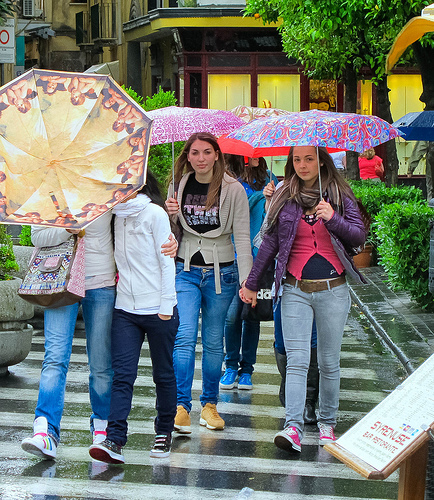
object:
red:
[402, 434, 411, 442]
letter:
[370, 420, 381, 432]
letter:
[376, 424, 388, 436]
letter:
[382, 424, 391, 438]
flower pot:
[0, 273, 35, 376]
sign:
[322, 352, 433, 483]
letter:
[398, 432, 413, 447]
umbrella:
[0, 67, 156, 232]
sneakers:
[148, 432, 173, 460]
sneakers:
[315, 419, 336, 448]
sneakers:
[21, 413, 59, 462]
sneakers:
[236, 371, 254, 392]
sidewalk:
[0, 266, 433, 498]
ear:
[212, 149, 219, 160]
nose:
[196, 151, 205, 165]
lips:
[193, 164, 209, 168]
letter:
[393, 432, 406, 445]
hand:
[162, 194, 181, 219]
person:
[88, 191, 182, 466]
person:
[161, 130, 256, 435]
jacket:
[242, 174, 368, 309]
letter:
[381, 440, 389, 449]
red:
[389, 434, 397, 442]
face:
[186, 137, 216, 173]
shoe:
[173, 402, 192, 434]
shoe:
[198, 399, 227, 432]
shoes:
[272, 421, 303, 453]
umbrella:
[143, 105, 247, 199]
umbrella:
[391, 111, 433, 141]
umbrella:
[214, 132, 345, 198]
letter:
[0, 29, 9, 45]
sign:
[0, 18, 15, 65]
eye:
[190, 148, 199, 156]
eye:
[202, 148, 211, 157]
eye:
[291, 155, 300, 163]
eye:
[304, 155, 315, 162]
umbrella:
[217, 109, 408, 209]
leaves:
[404, 228, 421, 241]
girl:
[239, 146, 369, 452]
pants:
[278, 275, 351, 436]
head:
[185, 129, 220, 175]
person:
[19, 210, 179, 458]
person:
[216, 151, 278, 389]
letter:
[373, 420, 385, 433]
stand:
[397, 441, 433, 499]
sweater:
[109, 194, 178, 319]